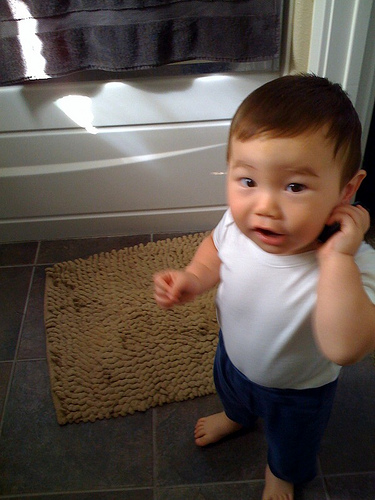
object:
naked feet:
[193, 411, 248, 447]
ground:
[0, 226, 375, 500]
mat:
[43, 228, 219, 426]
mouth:
[248, 224, 290, 247]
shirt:
[210, 203, 375, 391]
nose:
[252, 196, 285, 221]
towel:
[2, 0, 286, 87]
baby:
[151, 68, 375, 500]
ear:
[339, 166, 369, 206]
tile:
[0, 357, 156, 498]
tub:
[0, 75, 287, 248]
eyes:
[282, 179, 312, 199]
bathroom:
[1, 0, 375, 500]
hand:
[318, 202, 371, 256]